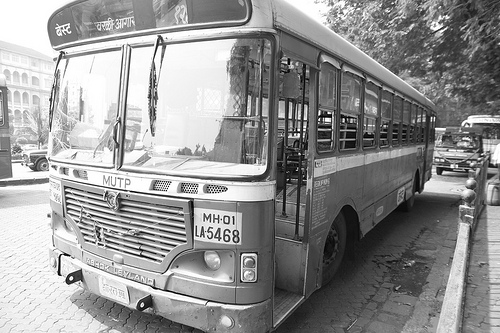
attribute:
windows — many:
[317, 50, 424, 146]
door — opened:
[269, 43, 321, 326]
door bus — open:
[260, 57, 322, 329]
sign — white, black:
[193, 209, 240, 245]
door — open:
[276, 50, 308, 331]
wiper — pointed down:
[140, 34, 170, 140]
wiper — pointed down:
[44, 50, 73, 131]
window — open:
[312, 57, 333, 152]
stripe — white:
[304, 138, 433, 177]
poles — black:
[280, 97, 302, 246]